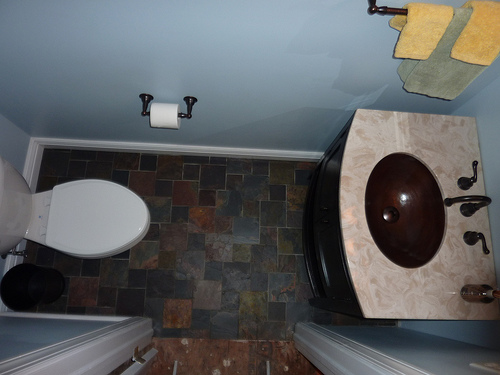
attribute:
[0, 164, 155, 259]
sink — toilet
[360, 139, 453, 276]
sink — nice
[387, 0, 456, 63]
towel — green,  yellow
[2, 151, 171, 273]
toilet — white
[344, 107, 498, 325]
sink — procelain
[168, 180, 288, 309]
floor — tiled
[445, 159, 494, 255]
facets — dark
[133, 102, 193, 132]
paper — white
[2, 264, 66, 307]
paper basket — brown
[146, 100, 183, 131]
tissue paper — brown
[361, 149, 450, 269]
sink — brown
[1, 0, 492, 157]
wall — white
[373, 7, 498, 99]
towel rack — modern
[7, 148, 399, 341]
floor — tile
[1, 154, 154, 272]
toilet — white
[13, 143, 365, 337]
floor — decorated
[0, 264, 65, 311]
trash can — black, small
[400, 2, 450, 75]
towel — yellow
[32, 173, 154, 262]
lid — down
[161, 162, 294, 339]
flooring — brick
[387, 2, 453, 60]
towel — brown 